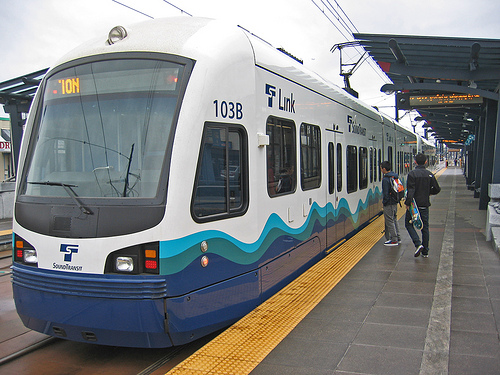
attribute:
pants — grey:
[383, 202, 401, 247]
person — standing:
[374, 159, 403, 245]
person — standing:
[402, 150, 439, 256]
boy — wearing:
[368, 144, 405, 258]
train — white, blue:
[11, 15, 438, 349]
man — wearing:
[378, 159, 404, 246]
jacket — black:
[403, 167, 438, 202]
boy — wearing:
[370, 158, 415, 253]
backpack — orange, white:
[387, 169, 411, 199]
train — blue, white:
[48, 41, 336, 295]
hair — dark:
[412, 151, 428, 164]